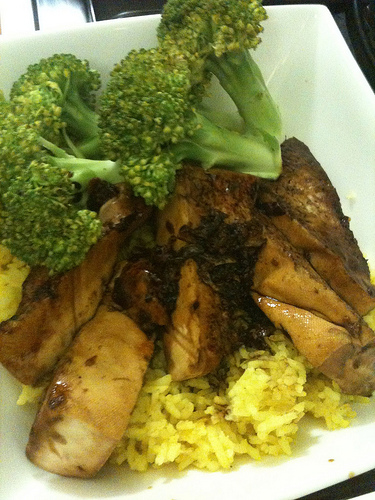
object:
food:
[0, 0, 375, 484]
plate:
[0, 0, 375, 499]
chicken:
[25, 305, 160, 484]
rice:
[259, 441, 282, 457]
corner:
[254, 1, 375, 141]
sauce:
[115, 216, 279, 350]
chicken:
[161, 246, 267, 393]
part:
[211, 442, 238, 467]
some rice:
[208, 409, 237, 448]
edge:
[0, 0, 312, 44]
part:
[116, 467, 156, 496]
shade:
[0, 369, 190, 500]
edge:
[40, 487, 158, 500]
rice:
[319, 394, 340, 413]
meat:
[149, 128, 375, 398]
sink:
[0, 0, 375, 500]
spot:
[256, 90, 264, 101]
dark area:
[25, 386, 70, 464]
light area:
[30, 419, 113, 480]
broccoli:
[99, 1, 292, 208]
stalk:
[95, 43, 282, 213]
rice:
[111, 449, 132, 467]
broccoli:
[0, 43, 104, 157]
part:
[298, 401, 374, 499]